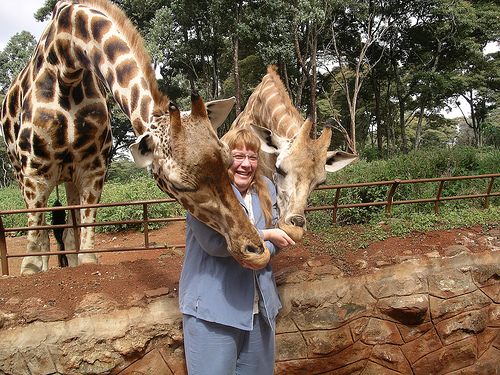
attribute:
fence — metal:
[314, 172, 498, 223]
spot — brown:
[41, 40, 74, 81]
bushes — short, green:
[0, 144, 475, 236]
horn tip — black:
[166, 100, 177, 112]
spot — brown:
[114, 57, 141, 88]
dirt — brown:
[28, 252, 190, 362]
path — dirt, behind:
[0, 222, 190, 276]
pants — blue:
[159, 250, 314, 373]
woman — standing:
[153, 54, 282, 374]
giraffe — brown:
[15, 8, 272, 290]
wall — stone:
[5, 230, 493, 374]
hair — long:
[212, 127, 274, 227]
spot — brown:
[33, 42, 48, 73]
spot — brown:
[104, 29, 134, 64]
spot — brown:
[48, 29, 107, 72]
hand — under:
[224, 216, 303, 262]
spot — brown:
[123, 81, 140, 115]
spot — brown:
[140, 77, 158, 86]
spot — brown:
[104, 35, 130, 67]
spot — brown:
[24, 176, 34, 189]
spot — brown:
[74, 123, 99, 139]